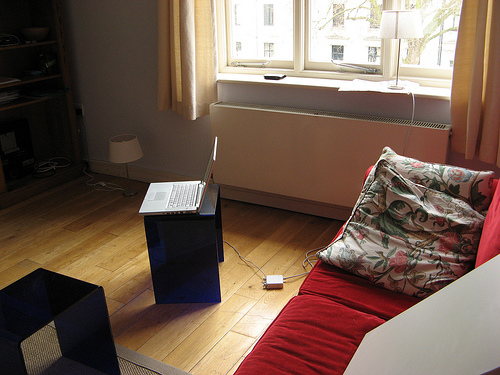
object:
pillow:
[344, 146, 495, 225]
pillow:
[319, 163, 487, 297]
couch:
[229, 150, 499, 374]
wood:
[142, 182, 225, 303]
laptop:
[137, 136, 217, 217]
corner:
[0, 0, 122, 200]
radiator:
[207, 100, 456, 208]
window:
[214, 2, 463, 78]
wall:
[88, 2, 183, 181]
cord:
[281, 241, 337, 283]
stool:
[0, 264, 123, 375]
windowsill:
[217, 69, 459, 95]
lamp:
[373, 4, 431, 95]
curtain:
[158, 0, 214, 123]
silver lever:
[328, 54, 386, 75]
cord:
[222, 238, 267, 279]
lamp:
[107, 124, 147, 199]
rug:
[22, 321, 199, 374]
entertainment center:
[0, 5, 90, 206]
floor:
[2, 167, 343, 373]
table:
[140, 184, 227, 308]